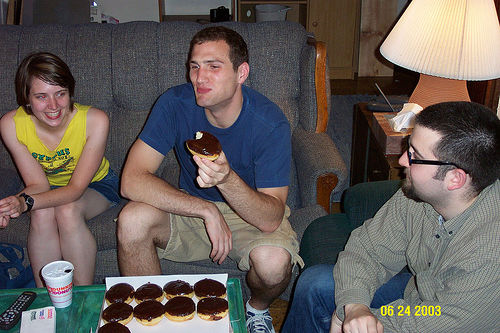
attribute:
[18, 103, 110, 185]
tanktop — yellow 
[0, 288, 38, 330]
remote control — black 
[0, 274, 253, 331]
table — green 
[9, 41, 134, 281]
woman — young 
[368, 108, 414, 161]
tissue box — brown 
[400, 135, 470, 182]
glasses — Black 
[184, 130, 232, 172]
doughnut — chocolate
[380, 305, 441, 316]
date stamp — yellow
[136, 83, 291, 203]
t-shirt — blue 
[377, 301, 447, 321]
stamp — yellow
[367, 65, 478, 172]
lamp — mauve 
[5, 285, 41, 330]
remote — Black 